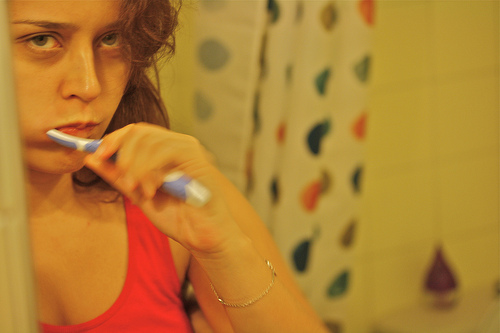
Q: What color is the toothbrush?
A: Purple and white.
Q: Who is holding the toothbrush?
A: The woman.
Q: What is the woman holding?
A: The toothbrush.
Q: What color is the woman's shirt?
A: Orange.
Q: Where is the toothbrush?
A: In the woman's hand.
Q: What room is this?
A: Bathroom.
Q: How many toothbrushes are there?
A: One.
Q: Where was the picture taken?
A: In a bathroom.